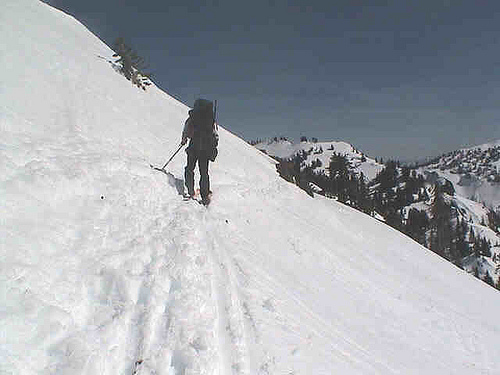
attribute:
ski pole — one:
[161, 142, 188, 176]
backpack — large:
[191, 98, 213, 160]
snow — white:
[0, 0, 498, 373]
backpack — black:
[182, 100, 225, 162]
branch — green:
[109, 32, 156, 92]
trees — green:
[242, 109, 471, 279]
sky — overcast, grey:
[98, 3, 497, 83]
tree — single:
[109, 33, 159, 95]